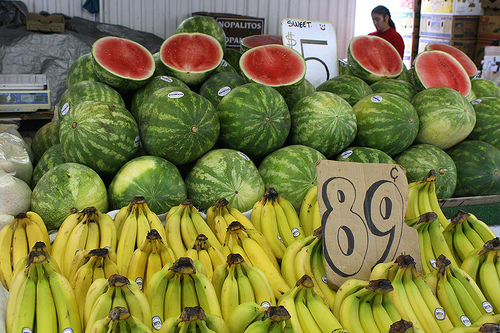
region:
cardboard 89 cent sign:
[312, 154, 421, 289]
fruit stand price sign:
[277, 15, 344, 105]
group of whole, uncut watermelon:
[56, 87, 283, 198]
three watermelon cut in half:
[84, 28, 312, 99]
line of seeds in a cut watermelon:
[411, 48, 476, 103]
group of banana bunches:
[4, 219, 301, 331]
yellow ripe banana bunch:
[372, 247, 447, 332]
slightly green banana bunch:
[4, 234, 88, 331]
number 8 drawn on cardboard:
[320, 154, 366, 284]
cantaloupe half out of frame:
[0, 167, 35, 221]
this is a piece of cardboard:
[300, 159, 487, 315]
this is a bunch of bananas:
[212, 211, 342, 316]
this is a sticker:
[143, 310, 175, 330]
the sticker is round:
[148, 297, 164, 326]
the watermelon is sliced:
[235, 44, 326, 89]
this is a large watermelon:
[158, 112, 284, 171]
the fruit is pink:
[258, 44, 303, 84]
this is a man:
[353, 17, 482, 70]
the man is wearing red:
[365, 2, 422, 77]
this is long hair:
[369, 2, 403, 20]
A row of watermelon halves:
[81, 26, 471, 91]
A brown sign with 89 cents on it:
[315, 153, 420, 283]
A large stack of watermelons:
[56, 66, 458, 173]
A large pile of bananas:
[19, 192, 323, 314]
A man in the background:
[366, 5, 407, 43]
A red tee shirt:
[362, 21, 403, 51]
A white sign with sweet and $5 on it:
[277, 17, 344, 83]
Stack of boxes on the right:
[418, 5, 480, 55]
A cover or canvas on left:
[7, 17, 97, 64]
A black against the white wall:
[201, 11, 279, 45]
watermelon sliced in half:
[81, 34, 163, 96]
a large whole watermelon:
[48, 95, 135, 162]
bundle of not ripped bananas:
[432, 262, 488, 322]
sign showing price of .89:
[304, 159, 421, 271]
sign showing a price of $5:
[275, 8, 349, 94]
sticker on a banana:
[431, 304, 448, 321]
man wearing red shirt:
[358, 9, 412, 46]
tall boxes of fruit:
[420, 0, 499, 50]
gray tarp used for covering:
[1, 4, 73, 76]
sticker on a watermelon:
[166, 86, 191, 112]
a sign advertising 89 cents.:
[309, 133, 432, 296]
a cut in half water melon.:
[407, 40, 474, 103]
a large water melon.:
[204, 79, 289, 161]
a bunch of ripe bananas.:
[247, 192, 303, 243]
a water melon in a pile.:
[46, 85, 148, 173]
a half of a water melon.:
[77, 33, 161, 79]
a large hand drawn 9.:
[364, 163, 408, 274]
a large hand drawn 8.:
[312, 165, 367, 297]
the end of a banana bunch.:
[170, 245, 204, 294]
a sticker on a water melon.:
[213, 80, 235, 100]